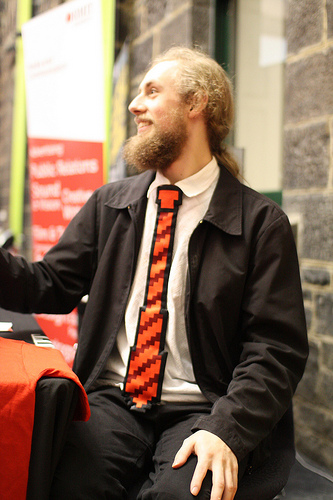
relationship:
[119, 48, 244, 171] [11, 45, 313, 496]
head of man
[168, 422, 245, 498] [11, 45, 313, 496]
hand of man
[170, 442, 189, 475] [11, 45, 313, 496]
thumb of man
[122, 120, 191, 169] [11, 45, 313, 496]
beard of man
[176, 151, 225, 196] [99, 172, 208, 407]
collar of shirt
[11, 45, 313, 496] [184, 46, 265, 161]
man with hair